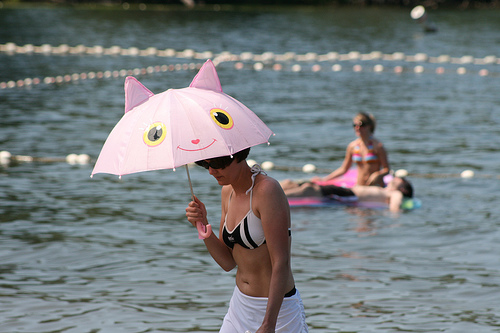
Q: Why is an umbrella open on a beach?
A: Sun Protection.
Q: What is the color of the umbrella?
A: Pink.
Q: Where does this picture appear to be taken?
A: A lake.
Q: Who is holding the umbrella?
A: Woman in bathing suit.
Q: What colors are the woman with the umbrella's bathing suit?
A: Black and white.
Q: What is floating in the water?
A: Buoys.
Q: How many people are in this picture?
A: Three.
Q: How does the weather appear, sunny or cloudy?
A: Sunny.